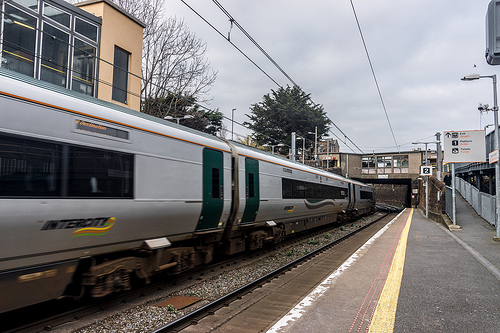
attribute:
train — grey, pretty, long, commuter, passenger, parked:
[1, 66, 378, 314]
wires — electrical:
[0, 0, 402, 158]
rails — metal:
[2, 202, 407, 332]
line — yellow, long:
[367, 207, 417, 332]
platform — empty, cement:
[392, 208, 498, 332]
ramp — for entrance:
[446, 181, 498, 269]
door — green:
[197, 147, 224, 230]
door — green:
[243, 156, 263, 223]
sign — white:
[443, 129, 487, 164]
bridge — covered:
[308, 150, 446, 207]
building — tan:
[1, 0, 145, 113]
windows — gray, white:
[0, 0, 98, 97]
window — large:
[1, 1, 37, 77]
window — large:
[39, 1, 72, 87]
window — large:
[69, 12, 103, 97]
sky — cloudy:
[67, 0, 498, 153]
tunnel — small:
[352, 177, 413, 208]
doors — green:
[195, 146, 262, 229]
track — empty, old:
[158, 207, 409, 332]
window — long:
[281, 177, 352, 203]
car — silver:
[1, 73, 234, 312]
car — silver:
[229, 141, 354, 256]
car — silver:
[352, 178, 378, 220]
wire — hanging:
[226, 14, 236, 41]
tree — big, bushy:
[243, 85, 335, 157]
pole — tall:
[456, 72, 499, 241]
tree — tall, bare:
[114, 0, 216, 120]